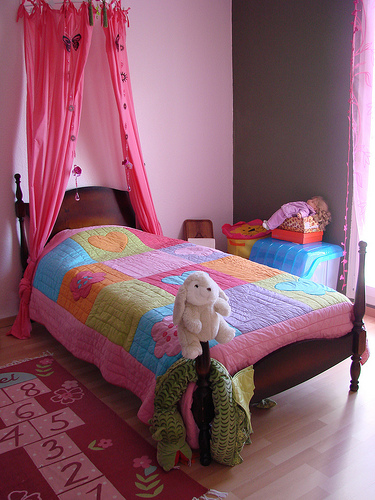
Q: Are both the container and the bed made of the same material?
A: No, the container is made of plastic and the bed is made of wood.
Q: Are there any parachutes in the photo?
A: No, there are no parachutes.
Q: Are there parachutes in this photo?
A: No, there are no parachutes.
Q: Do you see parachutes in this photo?
A: No, there are no parachutes.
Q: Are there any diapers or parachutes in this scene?
A: No, there are no parachutes or diapers.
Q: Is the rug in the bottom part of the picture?
A: Yes, the rug is in the bottom of the image.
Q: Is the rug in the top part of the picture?
A: No, the rug is in the bottom of the image.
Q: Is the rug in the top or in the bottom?
A: The rug is in the bottom of the image.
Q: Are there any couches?
A: No, there are no couches.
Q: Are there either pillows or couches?
A: No, there are no couches or pillows.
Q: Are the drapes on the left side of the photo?
A: No, the drapes are on the right of the image.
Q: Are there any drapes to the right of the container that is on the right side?
A: Yes, there are drapes to the right of the container.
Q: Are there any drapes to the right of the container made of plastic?
A: Yes, there are drapes to the right of the container.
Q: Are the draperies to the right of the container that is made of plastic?
A: Yes, the draperies are to the right of the container.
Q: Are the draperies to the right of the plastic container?
A: Yes, the draperies are to the right of the container.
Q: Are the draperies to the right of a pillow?
A: No, the draperies are to the right of the container.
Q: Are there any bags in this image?
A: No, there are no bags.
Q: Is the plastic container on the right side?
A: Yes, the container is on the right of the image.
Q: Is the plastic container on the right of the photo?
A: Yes, the container is on the right of the image.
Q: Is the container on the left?
A: No, the container is on the right of the image.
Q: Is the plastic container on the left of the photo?
A: No, the container is on the right of the image.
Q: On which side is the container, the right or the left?
A: The container is on the right of the image.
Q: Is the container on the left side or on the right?
A: The container is on the right of the image.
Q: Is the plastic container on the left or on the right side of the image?
A: The container is on the right of the image.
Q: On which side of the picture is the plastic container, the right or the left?
A: The container is on the right of the image.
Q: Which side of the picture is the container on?
A: The container is on the right of the image.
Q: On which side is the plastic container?
A: The container is on the right of the image.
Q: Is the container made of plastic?
A: Yes, the container is made of plastic.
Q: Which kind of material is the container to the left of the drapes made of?
A: The container is made of plastic.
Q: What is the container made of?
A: The container is made of plastic.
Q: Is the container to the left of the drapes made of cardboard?
A: No, the container is made of plastic.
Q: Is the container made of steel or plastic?
A: The container is made of plastic.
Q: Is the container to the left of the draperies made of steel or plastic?
A: The container is made of plastic.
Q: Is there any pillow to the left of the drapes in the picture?
A: No, there is a container to the left of the drapes.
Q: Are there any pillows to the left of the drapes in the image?
A: No, there is a container to the left of the drapes.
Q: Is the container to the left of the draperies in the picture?
A: Yes, the container is to the left of the draperies.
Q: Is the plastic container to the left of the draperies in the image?
A: Yes, the container is to the left of the draperies.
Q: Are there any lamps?
A: No, there are no lamps.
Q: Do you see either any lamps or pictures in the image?
A: No, there are no lamps or pictures.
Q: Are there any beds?
A: Yes, there is a bed.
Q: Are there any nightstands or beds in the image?
A: Yes, there is a bed.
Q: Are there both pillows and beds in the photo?
A: No, there is a bed but no pillows.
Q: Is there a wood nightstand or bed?
A: Yes, there is a wood bed.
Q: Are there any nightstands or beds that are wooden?
A: Yes, the bed is wooden.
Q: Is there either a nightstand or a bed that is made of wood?
A: Yes, the bed is made of wood.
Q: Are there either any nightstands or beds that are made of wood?
A: Yes, the bed is made of wood.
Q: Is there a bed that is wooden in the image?
A: Yes, there is a wood bed.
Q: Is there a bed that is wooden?
A: Yes, there is a bed that is wooden.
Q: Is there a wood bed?
A: Yes, there is a bed that is made of wood.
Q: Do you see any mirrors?
A: No, there are no mirrors.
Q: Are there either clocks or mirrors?
A: No, there are no mirrors or clocks.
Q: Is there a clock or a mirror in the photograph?
A: No, there are no mirrors or clocks.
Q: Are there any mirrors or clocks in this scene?
A: No, there are no mirrors or clocks.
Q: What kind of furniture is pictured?
A: The furniture is a bed.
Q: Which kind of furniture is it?
A: The piece of furniture is a bed.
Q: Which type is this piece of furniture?
A: This is a bed.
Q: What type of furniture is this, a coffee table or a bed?
A: This is a bed.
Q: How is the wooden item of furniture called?
A: The piece of furniture is a bed.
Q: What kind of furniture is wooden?
A: The furniture is a bed.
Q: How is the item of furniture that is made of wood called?
A: The piece of furniture is a bed.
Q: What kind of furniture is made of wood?
A: The furniture is a bed.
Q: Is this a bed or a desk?
A: This is a bed.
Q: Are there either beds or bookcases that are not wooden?
A: No, there is a bed but it is wooden.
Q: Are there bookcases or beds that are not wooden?
A: No, there is a bed but it is wooden.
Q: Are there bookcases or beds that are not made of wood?
A: No, there is a bed but it is made of wood.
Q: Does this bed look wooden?
A: Yes, the bed is wooden.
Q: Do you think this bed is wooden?
A: Yes, the bed is wooden.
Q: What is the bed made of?
A: The bed is made of wood.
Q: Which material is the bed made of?
A: The bed is made of wood.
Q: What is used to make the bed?
A: The bed is made of wood.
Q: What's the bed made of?
A: The bed is made of wood.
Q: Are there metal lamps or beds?
A: No, there is a bed but it is wooden.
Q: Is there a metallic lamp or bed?
A: No, there is a bed but it is wooden.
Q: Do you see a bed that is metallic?
A: No, there is a bed but it is wooden.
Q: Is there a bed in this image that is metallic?
A: No, there is a bed but it is wooden.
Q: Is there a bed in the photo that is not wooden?
A: No, there is a bed but it is wooden.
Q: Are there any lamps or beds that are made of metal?
A: No, there is a bed but it is made of wood.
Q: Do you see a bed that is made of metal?
A: No, there is a bed but it is made of wood.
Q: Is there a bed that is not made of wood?
A: No, there is a bed but it is made of wood.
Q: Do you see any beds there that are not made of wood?
A: No, there is a bed but it is made of wood.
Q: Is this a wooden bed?
A: Yes, this is a wooden bed.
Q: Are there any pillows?
A: No, there are no pillows.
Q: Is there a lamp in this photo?
A: No, there are no lamps.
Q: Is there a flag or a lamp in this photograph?
A: No, there are no lamps or flags.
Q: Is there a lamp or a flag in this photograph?
A: No, there are no lamps or flags.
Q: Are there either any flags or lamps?
A: No, there are no lamps or flags.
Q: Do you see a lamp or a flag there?
A: No, there are no lamps or flags.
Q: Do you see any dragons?
A: Yes, there is a dragon.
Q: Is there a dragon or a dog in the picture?
A: Yes, there is a dragon.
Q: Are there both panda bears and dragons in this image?
A: No, there is a dragon but no pandas.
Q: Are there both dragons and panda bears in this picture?
A: No, there is a dragon but no pandas.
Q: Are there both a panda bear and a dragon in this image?
A: No, there is a dragon but no pandas.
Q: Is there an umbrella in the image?
A: No, there are no umbrellas.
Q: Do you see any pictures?
A: No, there are no pictures.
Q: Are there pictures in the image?
A: No, there are no pictures.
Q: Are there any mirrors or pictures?
A: No, there are no pictures or mirrors.